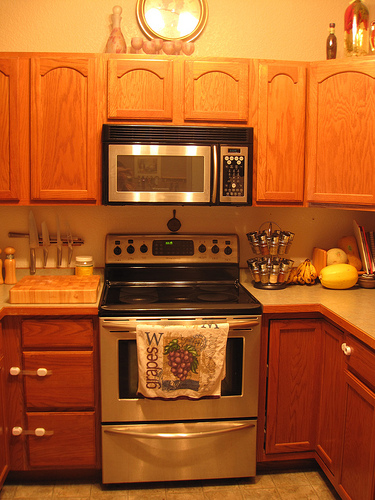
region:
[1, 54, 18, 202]
cabinet next to wooden cabinet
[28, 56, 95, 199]
cabinet next to wooden cabinet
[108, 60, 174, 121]
cabinet next to wooden cabinet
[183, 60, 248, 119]
cabinet next to wooden cabinet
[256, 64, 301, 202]
cabinet next to wooden cabinet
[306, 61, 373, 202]
cabinet next to wooden cabinet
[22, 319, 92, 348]
drawer on top of drawer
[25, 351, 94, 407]
drawer on top of drawer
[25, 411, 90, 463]
drawer below wooden drawer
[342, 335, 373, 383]
drawer on top of drawer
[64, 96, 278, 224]
a radio in top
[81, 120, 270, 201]
a ac in top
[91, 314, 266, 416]
a display of tv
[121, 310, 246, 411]
a cloth in front of table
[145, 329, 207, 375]
design on the cloth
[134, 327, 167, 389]
text in the cloth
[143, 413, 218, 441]
light falling on the object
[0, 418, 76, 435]
knob of the door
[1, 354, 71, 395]
handle of the door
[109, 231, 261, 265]
display of buttons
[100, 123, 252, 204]
A black and silver microwave.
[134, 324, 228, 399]
A towel on the front of an oven.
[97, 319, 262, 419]
A silver oven door.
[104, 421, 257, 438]
A bottom drawer silver handle on the oven.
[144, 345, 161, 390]
The word grapes on a hand towel.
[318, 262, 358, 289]
A large yellow squash on the counter.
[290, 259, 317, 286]
Ripe bunch of bananas on the counter.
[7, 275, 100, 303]
A very thick large chopping block.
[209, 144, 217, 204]
Silver handle of a microwave.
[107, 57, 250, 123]
Two small wood doors above a microwave.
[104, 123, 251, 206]
silver and black microwave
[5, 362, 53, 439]
safety locks on the kitchen drawers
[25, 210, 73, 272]
knives hanging on the wall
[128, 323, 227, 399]
dish towel with grapes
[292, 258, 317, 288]
yellow bananas with brown spots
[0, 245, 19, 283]
salt and pepper shakers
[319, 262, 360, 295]
yellow squash on the countertop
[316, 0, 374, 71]
decorative bottles on top of kitchen cabinets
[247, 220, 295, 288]
spice rack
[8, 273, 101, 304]
wooden cutting block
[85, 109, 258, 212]
microwave in kitchen cabinet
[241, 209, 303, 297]
spice rack sitting on kitchen cabinet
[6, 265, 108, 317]
chopping block on kitchen cabinet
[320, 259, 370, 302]
squash sitting on kitchen cabinet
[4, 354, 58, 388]
drawer knobs on front of kitchen drawers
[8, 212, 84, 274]
knives mounted on kitchen wall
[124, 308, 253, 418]
hand towel on front of stove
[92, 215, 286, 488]
stainless steel stove in kitchen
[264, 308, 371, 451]
wooden cabinet front in kitchen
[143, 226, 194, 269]
digit clock on top of stove